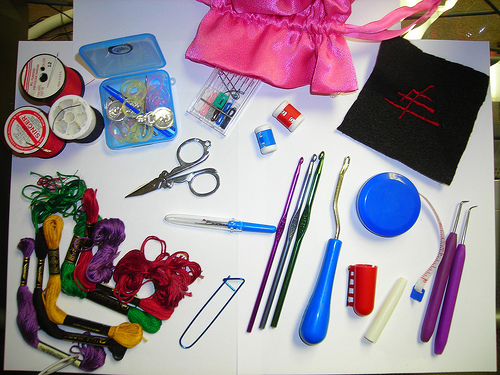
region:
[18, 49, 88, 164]
spools of thread laying on the table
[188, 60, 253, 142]
a small sewing kit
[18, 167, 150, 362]
a bunch of cross stitch thread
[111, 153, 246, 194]
a pair of silver sewing shears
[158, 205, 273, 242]
a container of sewing needles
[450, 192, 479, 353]
cross stitch hooks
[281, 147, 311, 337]
knitting needles laying on the table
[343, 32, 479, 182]
a black piece of cloth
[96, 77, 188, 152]
sewing kit with buttons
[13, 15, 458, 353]
a table full of sewing items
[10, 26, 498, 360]
craft supplies on a table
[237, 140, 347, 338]
three crochet needles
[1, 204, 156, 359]
different colored strings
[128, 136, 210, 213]
silver craft scissors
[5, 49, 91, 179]
rolls of colorful thread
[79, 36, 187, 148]
little blue box of bands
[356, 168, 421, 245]
little round object with a blue top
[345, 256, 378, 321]
red thumb thimble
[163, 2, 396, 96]
shiny pink clothe with wrinkles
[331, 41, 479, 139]
black cloth with red writing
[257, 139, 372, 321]
three crochet hooks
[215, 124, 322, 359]
three crochet hooks next to each other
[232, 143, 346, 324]
crochet hook on a table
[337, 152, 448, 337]
a tape measure on the table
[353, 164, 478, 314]
a blue tape measure on the table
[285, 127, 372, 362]
a latch hook on the table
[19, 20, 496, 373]
a table with craft supplies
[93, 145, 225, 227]
metal scissors on the table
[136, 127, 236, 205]
small metal scissors on the table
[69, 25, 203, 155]
a blue box on the table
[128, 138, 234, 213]
One pair of scissors on the table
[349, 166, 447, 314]
a blue and white measuring tape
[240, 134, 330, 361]
Three crochet hooks lined up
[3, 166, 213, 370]
different colors of string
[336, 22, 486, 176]
A little black bag with red japanese letters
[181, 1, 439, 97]
a pink piece of cloth with ties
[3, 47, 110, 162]
Three spools of thread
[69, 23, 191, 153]
a blue container is open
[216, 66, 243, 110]
a safety pin in a clear box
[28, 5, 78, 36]
a thick white cord on the floor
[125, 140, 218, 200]
small pair of scisors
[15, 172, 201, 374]
several strands of cross stick floss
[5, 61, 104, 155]
three spools of thread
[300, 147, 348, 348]
latch hook hook with blue handle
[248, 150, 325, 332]
three knitting needles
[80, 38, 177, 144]
clear blue box with sewing supplies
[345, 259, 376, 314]
red thimble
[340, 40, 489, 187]
black fabric with red stiching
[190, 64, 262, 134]
clear case with needles and a safety pin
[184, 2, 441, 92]
pink silk bag with a ribbon drawstring